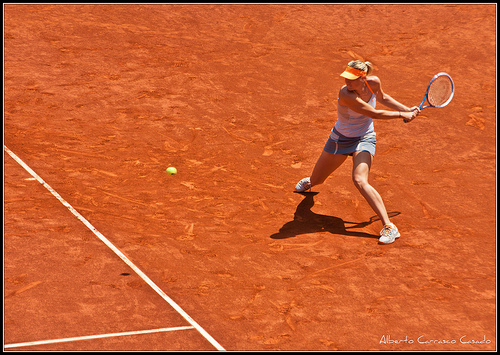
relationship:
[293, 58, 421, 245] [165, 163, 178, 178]
player hitting ball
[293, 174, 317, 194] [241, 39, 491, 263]
shoe of player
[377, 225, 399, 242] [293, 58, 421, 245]
left shoe of player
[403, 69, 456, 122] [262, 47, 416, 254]
racket of tennis player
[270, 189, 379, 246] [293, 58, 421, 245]
shadow of player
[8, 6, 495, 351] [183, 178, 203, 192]
turf has footprint